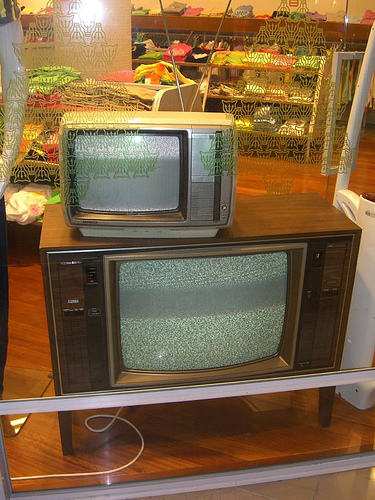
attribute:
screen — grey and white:
[110, 249, 291, 373]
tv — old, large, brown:
[36, 190, 362, 457]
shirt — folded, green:
[137, 50, 164, 60]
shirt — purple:
[309, 9, 330, 20]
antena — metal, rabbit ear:
[199, 48, 219, 78]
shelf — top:
[0, 71, 207, 229]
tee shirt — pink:
[164, 39, 191, 63]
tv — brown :
[49, 91, 307, 293]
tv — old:
[63, 108, 236, 242]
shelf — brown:
[201, 40, 345, 163]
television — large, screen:
[42, 92, 253, 240]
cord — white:
[7, 412, 146, 478]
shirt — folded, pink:
[165, 40, 190, 62]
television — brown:
[95, 245, 307, 378]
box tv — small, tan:
[53, 106, 248, 241]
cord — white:
[7, 401, 150, 484]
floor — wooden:
[0, 150, 374, 488]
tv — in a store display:
[10, 93, 357, 382]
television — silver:
[56, 108, 238, 241]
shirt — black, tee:
[5, 150, 70, 237]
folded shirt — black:
[183, 44, 212, 62]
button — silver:
[219, 204, 228, 213]